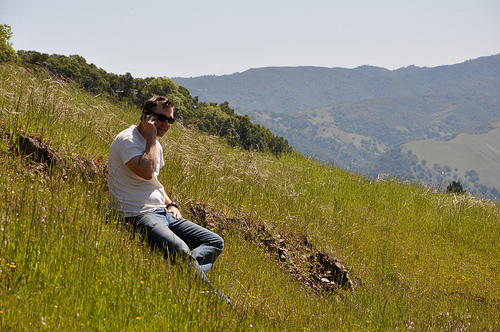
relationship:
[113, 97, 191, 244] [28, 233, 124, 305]
man in grass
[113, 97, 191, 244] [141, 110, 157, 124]
man on phone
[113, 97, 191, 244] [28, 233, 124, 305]
man on grass